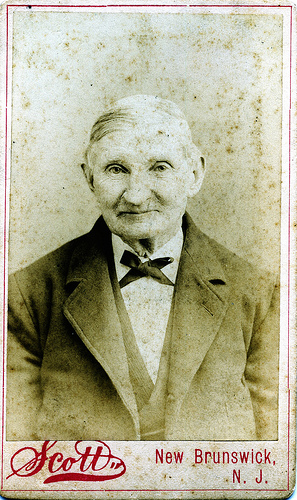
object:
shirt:
[113, 235, 185, 374]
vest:
[104, 230, 174, 440]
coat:
[8, 213, 277, 441]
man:
[9, 94, 285, 438]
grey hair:
[84, 95, 201, 166]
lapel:
[178, 224, 230, 380]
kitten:
[153, 447, 271, 483]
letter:
[192, 448, 271, 464]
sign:
[2, 440, 277, 494]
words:
[6, 440, 126, 483]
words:
[153, 448, 183, 462]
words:
[193, 448, 271, 464]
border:
[5, 5, 290, 486]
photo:
[9, 11, 288, 497]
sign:
[7, 6, 289, 443]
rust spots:
[145, 463, 219, 493]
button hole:
[195, 295, 213, 329]